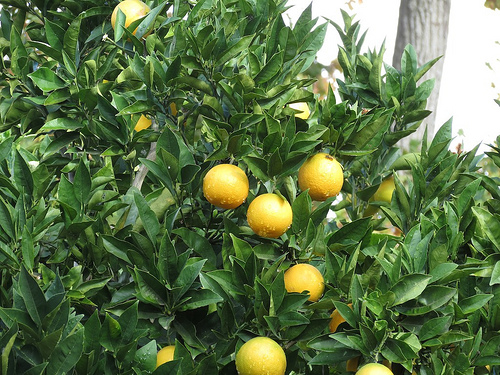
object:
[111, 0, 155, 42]
lemons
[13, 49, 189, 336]
branch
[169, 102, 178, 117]
lemons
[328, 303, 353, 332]
lemons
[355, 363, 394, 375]
lemons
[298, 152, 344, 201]
lemon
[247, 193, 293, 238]
lemon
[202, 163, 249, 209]
lemon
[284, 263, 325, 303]
lemon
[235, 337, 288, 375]
lemon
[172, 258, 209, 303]
leaf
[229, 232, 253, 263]
leaf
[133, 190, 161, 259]
leaf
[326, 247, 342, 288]
leaf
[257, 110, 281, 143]
leaf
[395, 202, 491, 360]
branch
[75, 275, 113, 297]
leaves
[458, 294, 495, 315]
leaves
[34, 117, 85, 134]
leaves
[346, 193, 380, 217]
lemons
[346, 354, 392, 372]
lemons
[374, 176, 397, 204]
lemons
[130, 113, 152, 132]
lemons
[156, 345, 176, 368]
lemons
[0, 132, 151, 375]
tree